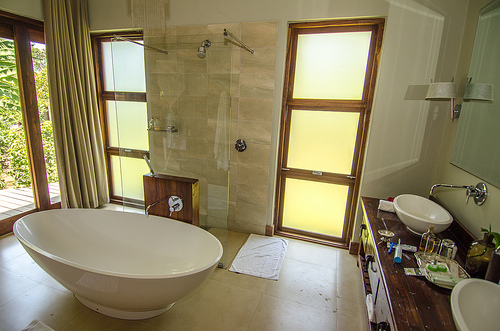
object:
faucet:
[428, 181, 486, 205]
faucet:
[144, 194, 186, 217]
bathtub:
[12, 207, 223, 320]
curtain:
[42, 0, 112, 209]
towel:
[228, 229, 290, 283]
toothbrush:
[392, 237, 404, 262]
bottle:
[417, 223, 437, 253]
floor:
[0, 199, 370, 330]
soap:
[148, 117, 163, 131]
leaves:
[1, 37, 58, 190]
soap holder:
[164, 125, 179, 133]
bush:
[0, 38, 57, 190]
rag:
[365, 292, 375, 322]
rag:
[375, 196, 395, 214]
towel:
[19, 315, 54, 330]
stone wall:
[142, 21, 278, 233]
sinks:
[391, 192, 499, 330]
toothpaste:
[385, 242, 416, 253]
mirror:
[448, 0, 498, 188]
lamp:
[425, 78, 460, 119]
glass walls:
[105, 32, 231, 265]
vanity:
[355, 196, 477, 331]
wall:
[435, 4, 499, 252]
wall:
[75, 0, 385, 253]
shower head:
[195, 36, 212, 62]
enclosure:
[109, 23, 289, 250]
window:
[0, 24, 38, 213]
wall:
[141, 20, 280, 233]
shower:
[116, 23, 285, 243]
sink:
[391, 193, 453, 238]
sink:
[449, 272, 499, 330]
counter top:
[432, 173, 500, 213]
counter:
[357, 195, 499, 330]